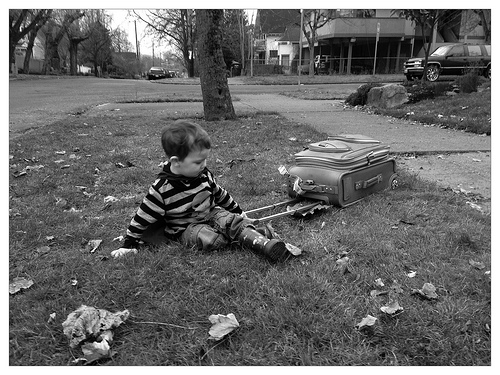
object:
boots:
[238, 227, 292, 263]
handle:
[354, 173, 381, 191]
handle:
[301, 180, 337, 195]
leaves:
[406, 269, 415, 278]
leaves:
[59, 161, 71, 169]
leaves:
[447, 183, 481, 200]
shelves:
[370, 23, 379, 74]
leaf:
[208, 314, 240, 342]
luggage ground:
[254, 127, 424, 257]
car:
[402, 38, 499, 83]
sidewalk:
[246, 81, 494, 212]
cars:
[144, 67, 175, 78]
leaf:
[415, 282, 438, 300]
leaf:
[335, 252, 353, 274]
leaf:
[356, 314, 376, 330]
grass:
[407, 72, 487, 132]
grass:
[239, 74, 403, 87]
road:
[6, 70, 403, 127]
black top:
[246, 88, 485, 230]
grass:
[9, 93, 486, 365]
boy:
[111, 119, 288, 263]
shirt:
[118, 162, 242, 249]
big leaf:
[57, 302, 131, 365]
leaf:
[284, 242, 301, 256]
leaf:
[9, 275, 36, 292]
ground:
[12, 75, 490, 365]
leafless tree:
[298, 8, 333, 81]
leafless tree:
[58, 8, 101, 74]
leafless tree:
[40, 4, 90, 73]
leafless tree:
[8, 11, 27, 64]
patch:
[69, 114, 354, 374]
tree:
[182, 0, 248, 126]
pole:
[134, 20, 139, 72]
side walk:
[254, 95, 487, 229]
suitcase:
[271, 130, 403, 210]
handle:
[237, 195, 323, 222]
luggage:
[237, 135, 401, 224]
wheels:
[391, 178, 399, 189]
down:
[152, 234, 388, 375]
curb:
[236, 254, 390, 375]